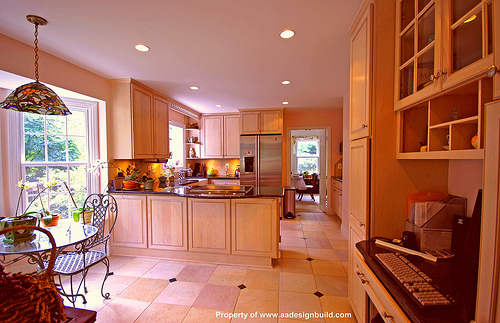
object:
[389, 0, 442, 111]
cabinets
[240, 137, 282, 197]
refrigerator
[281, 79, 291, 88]
lighting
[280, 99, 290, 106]
lighting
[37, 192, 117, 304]
chair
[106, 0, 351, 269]
kitchen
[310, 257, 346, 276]
tan tile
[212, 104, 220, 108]
kitchen lighting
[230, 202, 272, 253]
cabinet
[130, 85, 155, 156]
cabinet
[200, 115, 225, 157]
cabinet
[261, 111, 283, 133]
cabinet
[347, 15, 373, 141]
cabinet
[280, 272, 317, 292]
tile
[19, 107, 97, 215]
patio door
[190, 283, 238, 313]
tile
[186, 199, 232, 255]
kitchen cabinets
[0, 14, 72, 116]
lamp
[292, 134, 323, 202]
dining room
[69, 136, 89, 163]
window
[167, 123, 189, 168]
window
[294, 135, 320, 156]
window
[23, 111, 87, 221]
yard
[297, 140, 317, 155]
yard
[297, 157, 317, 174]
yard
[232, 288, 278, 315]
tiles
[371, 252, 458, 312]
keyboard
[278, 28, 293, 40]
kitchen lighting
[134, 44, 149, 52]
kitchen lighting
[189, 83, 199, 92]
kitchen lighting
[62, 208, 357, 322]
floor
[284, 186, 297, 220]
trash can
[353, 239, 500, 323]
desk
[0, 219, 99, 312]
table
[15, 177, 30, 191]
flowers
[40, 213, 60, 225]
pot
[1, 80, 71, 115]
stained glass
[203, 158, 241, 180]
backsplash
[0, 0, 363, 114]
ceiling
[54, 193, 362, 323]
floor